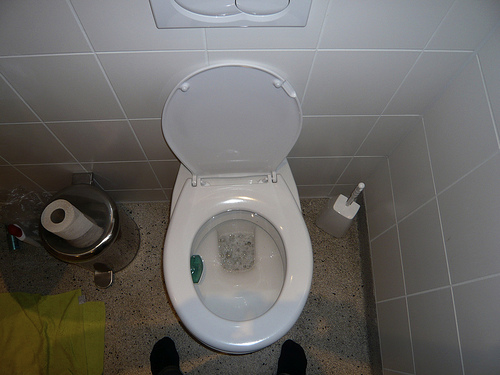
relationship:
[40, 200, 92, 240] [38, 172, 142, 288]
toilet paper on can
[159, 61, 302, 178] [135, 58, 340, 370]
lid on toilet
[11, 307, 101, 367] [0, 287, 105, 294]
towel on floor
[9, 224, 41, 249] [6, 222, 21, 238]
item with top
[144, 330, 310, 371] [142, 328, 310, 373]
feet with socks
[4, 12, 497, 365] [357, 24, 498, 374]
bathroom with wall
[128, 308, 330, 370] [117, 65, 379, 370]
feet near toilet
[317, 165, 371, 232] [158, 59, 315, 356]
brush next to toilet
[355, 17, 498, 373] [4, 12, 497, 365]
wall in bathroom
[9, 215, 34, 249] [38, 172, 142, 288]
item near can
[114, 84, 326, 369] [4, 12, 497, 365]
toilet in bathroom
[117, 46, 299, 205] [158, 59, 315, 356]
lid on toilet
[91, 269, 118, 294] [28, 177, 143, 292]
step latch on can